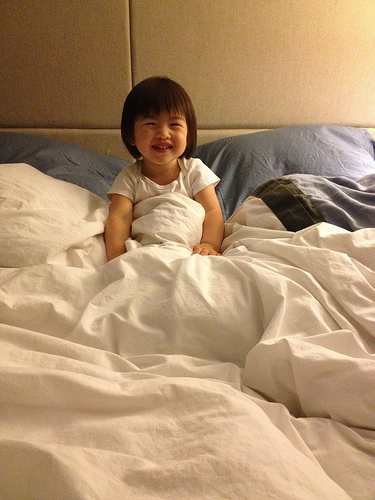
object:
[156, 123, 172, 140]
nose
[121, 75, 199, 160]
hair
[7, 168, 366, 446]
covers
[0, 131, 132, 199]
pillow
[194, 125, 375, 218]
pillow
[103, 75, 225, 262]
child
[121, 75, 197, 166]
child's head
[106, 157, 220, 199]
shirt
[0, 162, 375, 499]
blanket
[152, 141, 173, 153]
mouth